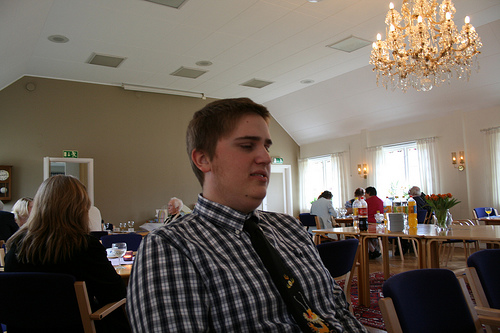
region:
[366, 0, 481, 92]
Hanging light in a room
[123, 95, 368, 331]
A guy wearing a plaid shirt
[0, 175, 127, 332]
Woman sitting in a chair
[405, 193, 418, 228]
Bottle of a soft drink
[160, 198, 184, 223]
Old man sitting in a room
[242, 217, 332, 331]
A fancy tie being worn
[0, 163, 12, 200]
A piece of wall furniture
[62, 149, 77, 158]
A green exit sign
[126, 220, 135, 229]
A glass on a table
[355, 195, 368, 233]
A bottle of cola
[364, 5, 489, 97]
chandelier on ceiling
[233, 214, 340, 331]
black tie around neck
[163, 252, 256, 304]
checkered pattern on shirt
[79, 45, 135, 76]
vent on ceiling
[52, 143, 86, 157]
sign on top of door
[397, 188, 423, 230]
orange beverage in bottle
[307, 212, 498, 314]
wooden table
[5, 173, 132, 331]
woman sitting in wooden chair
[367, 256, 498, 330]
blue cushion chair with wooden arms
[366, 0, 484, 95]
gold yellow and white chandelier hanging from ceiling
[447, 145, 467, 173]
yellow glass light on wall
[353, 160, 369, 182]
yellow glass light on wall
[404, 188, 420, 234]
plastic orange soda bottle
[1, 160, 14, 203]
rectangular wooden clock on wall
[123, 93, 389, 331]
man wearing black tie and black blue and white shirt sitting in chair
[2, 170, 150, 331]
woman wearing black shirt sitting at table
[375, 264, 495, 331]
dark blue chair with light brown wooden frame and arms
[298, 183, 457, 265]
people sitting around circular table near wall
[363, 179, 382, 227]
This is a person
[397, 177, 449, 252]
This is a person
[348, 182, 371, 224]
This is a person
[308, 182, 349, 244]
This is a person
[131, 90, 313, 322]
This is a person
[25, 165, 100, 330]
This is a person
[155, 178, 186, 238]
This is a person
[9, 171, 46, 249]
This is a person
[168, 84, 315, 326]
This is a person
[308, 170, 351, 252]
This is a person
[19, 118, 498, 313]
room with people at event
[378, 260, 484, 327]
chair at a table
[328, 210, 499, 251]
table with items on it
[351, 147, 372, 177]
light on the wall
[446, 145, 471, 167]
light on the wall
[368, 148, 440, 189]
window in the room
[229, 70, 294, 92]
vent on the ceiling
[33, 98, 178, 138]
wall on one side of room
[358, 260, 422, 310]
rug under the table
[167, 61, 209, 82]
large white air vent in the ceiling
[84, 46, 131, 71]
large white air vent in the ceiling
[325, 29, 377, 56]
large white air vent in the ceiling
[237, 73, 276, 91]
large white air vent in the ceiling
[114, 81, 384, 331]
a person with double chin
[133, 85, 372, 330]
the person is wearing a dress shirt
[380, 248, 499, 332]
the chairs are blue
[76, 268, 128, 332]
the arms are wood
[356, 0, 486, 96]
the light is lit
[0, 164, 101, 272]
the hair is long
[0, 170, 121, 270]
the hair is blonde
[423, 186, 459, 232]
orange flowers in a vase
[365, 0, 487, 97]
A chandelier hanging from the ceiling